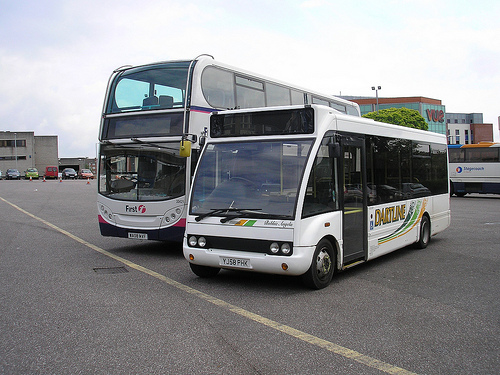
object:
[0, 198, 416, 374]
line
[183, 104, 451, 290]
bus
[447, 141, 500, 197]
bus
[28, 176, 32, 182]
orange cones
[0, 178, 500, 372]
parking lot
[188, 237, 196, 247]
headlights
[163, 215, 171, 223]
lights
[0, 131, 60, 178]
building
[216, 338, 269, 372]
concrete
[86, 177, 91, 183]
cone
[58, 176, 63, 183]
cone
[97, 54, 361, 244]
bus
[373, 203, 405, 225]
dartline